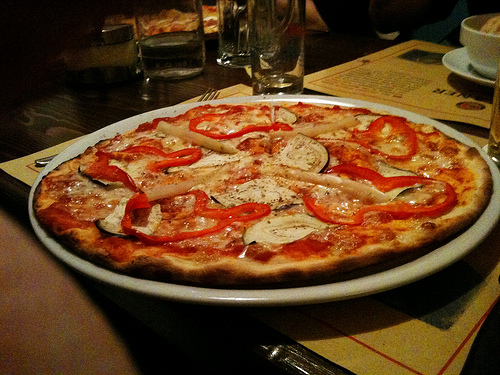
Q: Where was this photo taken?
A: A restaurant.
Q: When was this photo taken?
A: During a mealtime.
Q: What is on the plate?
A: Pizza.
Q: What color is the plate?
A: White.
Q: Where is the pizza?
A: On the plate.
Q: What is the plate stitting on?
A: A table.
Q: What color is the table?
A: Brown.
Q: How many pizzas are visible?
A: One.